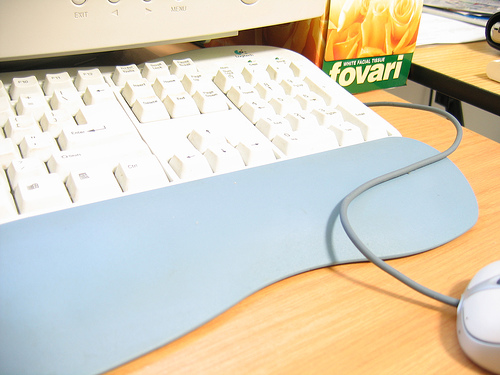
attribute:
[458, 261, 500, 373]
mouse — white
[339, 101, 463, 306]
cord — gray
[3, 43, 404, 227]
keyboard — white, slanted, blue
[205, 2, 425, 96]
box — white, yellow, green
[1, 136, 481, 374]
pad — blue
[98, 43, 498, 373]
table — wood, tan, oak, wooden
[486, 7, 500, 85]
camera — black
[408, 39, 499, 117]
table — surface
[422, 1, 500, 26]
notebook — white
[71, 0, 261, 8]
buttons — small, white, round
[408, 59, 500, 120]
trim — black